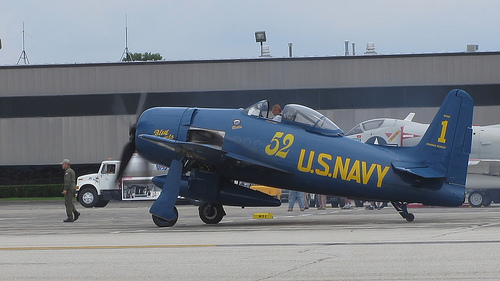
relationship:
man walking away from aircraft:
[58, 160, 81, 223] [115, 87, 475, 226]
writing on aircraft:
[248, 125, 420, 211] [115, 87, 475, 226]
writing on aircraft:
[435, 119, 447, 143] [115, 87, 475, 226]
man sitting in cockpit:
[271, 102, 286, 122] [248, 98, 344, 135]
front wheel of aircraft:
[195, 198, 226, 226] [115, 87, 475, 226]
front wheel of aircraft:
[151, 202, 180, 228] [115, 87, 475, 226]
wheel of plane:
[405, 208, 416, 220] [124, 88, 478, 237]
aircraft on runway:
[115, 87, 475, 226] [0, 200, 499, 279]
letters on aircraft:
[293, 141, 395, 192] [115, 87, 475, 226]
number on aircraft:
[258, 120, 293, 167] [115, 87, 475, 226]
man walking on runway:
[58, 160, 81, 223] [0, 200, 499, 279]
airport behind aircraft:
[1, 14, 498, 195] [115, 87, 475, 226]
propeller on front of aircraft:
[104, 75, 150, 187] [115, 87, 475, 226]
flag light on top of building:
[255, 30, 265, 42] [0, 42, 499, 187]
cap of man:
[52, 158, 79, 170] [57, 155, 81, 224]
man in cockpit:
[271, 102, 286, 122] [249, 95, 336, 135]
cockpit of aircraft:
[249, 95, 336, 135] [115, 87, 475, 226]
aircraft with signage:
[115, 87, 475, 226] [297, 140, 389, 189]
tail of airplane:
[419, 90, 477, 173] [106, 86, 498, 234]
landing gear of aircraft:
[144, 165, 279, 227] [115, 87, 475, 226]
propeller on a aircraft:
[104, 75, 150, 187] [115, 87, 475, 226]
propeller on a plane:
[104, 75, 150, 187] [341, 110, 498, 207]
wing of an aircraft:
[134, 129, 289, 180] [115, 87, 475, 226]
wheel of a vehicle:
[74, 185, 100, 207] [72, 152, 129, 224]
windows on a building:
[5, 158, 61, 188] [9, 51, 182, 234]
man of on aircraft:
[271, 102, 286, 122] [115, 87, 475, 226]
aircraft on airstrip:
[115, 87, 475, 226] [0, 200, 498, 279]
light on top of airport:
[465, 42, 481, 55] [11, 31, 488, 277]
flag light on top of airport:
[255, 30, 264, 57] [11, 31, 488, 277]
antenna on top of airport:
[6, 16, 63, 62] [11, 31, 488, 277]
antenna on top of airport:
[92, 11, 189, 70] [11, 31, 488, 277]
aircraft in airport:
[115, 87, 475, 226] [0, 32, 490, 246]